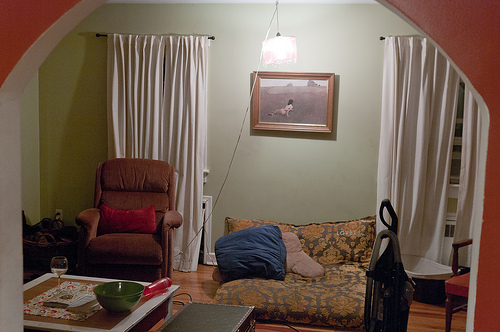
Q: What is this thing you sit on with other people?
A: Couch.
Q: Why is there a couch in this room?
A: To sit on.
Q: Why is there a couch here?
A: Sit on.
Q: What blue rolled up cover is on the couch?
A: Blanket.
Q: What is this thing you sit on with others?
A: Couch.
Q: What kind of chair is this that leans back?
A: Recliner.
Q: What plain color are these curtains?
A: White.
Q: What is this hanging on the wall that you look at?
A: Picture.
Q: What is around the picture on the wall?
A: Frame.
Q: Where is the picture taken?
A: A living room.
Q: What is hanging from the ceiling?
A: A light.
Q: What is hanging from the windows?
A: Curtains.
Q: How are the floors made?
A: Of wood.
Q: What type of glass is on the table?
A: Wine.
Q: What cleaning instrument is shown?
A: A vacuum.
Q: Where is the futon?
A: In between the windows.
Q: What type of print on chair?
A: Beige and gold.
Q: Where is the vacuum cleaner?
A: In the room with the hose.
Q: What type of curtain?
A: White curtain.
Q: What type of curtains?
A: Closed and white.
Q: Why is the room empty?
A: There is no one.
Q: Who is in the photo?
A: No one.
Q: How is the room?
A: Neat.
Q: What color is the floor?
A: Brown.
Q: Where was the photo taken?
A: Living room.